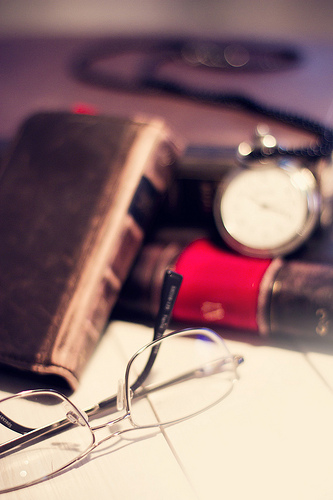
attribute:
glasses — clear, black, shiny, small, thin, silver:
[2, 271, 214, 456]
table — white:
[101, 320, 288, 497]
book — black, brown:
[15, 103, 132, 344]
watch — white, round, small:
[204, 150, 333, 256]